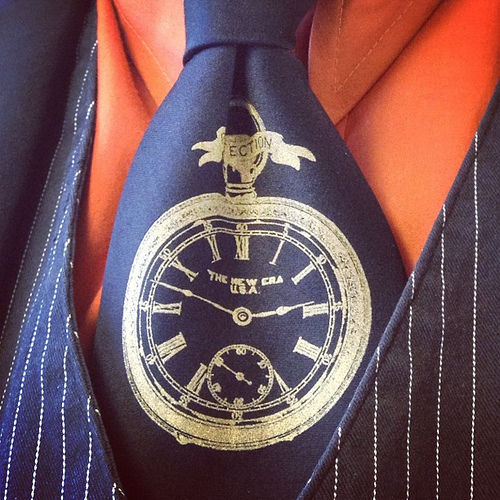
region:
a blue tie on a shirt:
[97, 3, 393, 495]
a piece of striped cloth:
[330, 310, 499, 475]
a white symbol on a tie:
[115, 171, 365, 451]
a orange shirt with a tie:
[107, 0, 472, 185]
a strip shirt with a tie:
[5, 55, 465, 456]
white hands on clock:
[137, 272, 342, 323]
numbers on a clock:
[285, 330, 328, 375]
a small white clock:
[195, 347, 293, 404]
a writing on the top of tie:
[200, 115, 288, 207]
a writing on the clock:
[199, 263, 295, 302]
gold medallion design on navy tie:
[121, 195, 371, 457]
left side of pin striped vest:
[296, 85, 496, 492]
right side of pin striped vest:
[4, 3, 128, 496]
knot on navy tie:
[178, 0, 317, 77]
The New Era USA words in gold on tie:
[205, 268, 288, 297]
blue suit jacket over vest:
[2, 0, 117, 305]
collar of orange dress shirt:
[89, 0, 456, 157]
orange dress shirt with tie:
[69, 0, 496, 355]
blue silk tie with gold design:
[91, 0, 404, 490]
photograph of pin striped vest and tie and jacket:
[5, 3, 499, 497]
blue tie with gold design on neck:
[96, 0, 416, 495]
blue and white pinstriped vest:
[6, 2, 496, 498]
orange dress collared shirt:
[59, 0, 499, 355]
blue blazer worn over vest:
[1, 0, 143, 336]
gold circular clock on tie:
[124, 129, 384, 442]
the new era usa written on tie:
[200, 265, 290, 299]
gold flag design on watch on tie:
[203, 93, 315, 198]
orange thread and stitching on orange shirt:
[323, 0, 424, 107]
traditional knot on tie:
[171, 5, 318, 80]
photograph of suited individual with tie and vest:
[8, 19, 498, 493]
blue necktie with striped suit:
[91, 2, 406, 497]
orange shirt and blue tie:
[37, 1, 497, 498]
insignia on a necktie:
[113, 91, 371, 455]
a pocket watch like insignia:
[120, 196, 371, 451]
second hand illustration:
[205, 344, 275, 411]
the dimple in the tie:
[187, 44, 316, 193]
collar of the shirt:
[308, 2, 443, 129]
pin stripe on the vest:
[373, 357, 381, 499]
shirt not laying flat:
[80, 0, 157, 210]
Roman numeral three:
[290, 332, 322, 362]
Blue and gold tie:
[124, 53, 346, 303]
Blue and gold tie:
[125, 105, 382, 476]